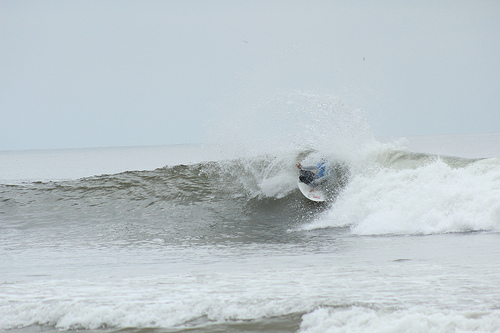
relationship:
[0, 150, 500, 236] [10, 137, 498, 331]
waves are crashing in water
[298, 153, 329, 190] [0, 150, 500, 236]
surfer riding waves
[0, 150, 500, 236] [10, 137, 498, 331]
waves are in water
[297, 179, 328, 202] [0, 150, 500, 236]
surfboard on waves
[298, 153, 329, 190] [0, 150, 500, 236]
surfer on waves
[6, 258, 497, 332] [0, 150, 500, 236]
foamy water in front of waves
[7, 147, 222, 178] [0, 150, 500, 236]
calm waters are behind waves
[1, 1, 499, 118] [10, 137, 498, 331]
sky above water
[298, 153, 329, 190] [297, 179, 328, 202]
surfer on surfboard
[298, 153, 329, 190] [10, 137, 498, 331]
surfer in water